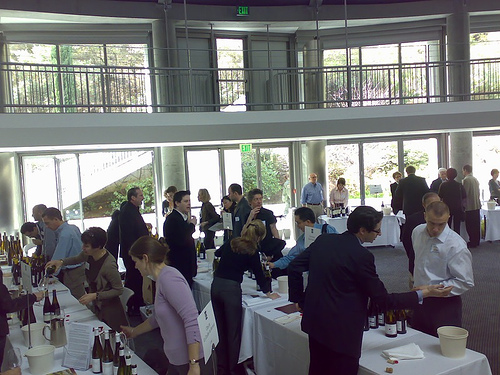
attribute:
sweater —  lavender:
[151, 261, 208, 365]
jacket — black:
[284, 225, 425, 372]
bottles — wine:
[367, 287, 412, 339]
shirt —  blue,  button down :
[302, 182, 324, 202]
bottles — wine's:
[385, 295, 438, 326]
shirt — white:
[404, 225, 475, 296]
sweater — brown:
[61, 244, 163, 322]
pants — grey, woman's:
[197, 277, 258, 373]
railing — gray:
[213, 70, 260, 110]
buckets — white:
[421, 306, 485, 373]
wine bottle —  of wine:
[380, 309, 397, 341]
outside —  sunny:
[38, 132, 405, 180]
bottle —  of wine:
[37, 290, 54, 345]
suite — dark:
[269, 188, 431, 365]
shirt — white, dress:
[409, 218, 476, 303]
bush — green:
[242, 152, 279, 194]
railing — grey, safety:
[0, 53, 499, 115]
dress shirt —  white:
[410, 226, 478, 309]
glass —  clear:
[116, 319, 129, 358]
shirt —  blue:
[298, 179, 323, 211]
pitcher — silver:
[9, 274, 104, 363]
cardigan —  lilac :
[151, 272, 203, 342]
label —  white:
[381, 321, 402, 336]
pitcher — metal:
[41, 314, 68, 349]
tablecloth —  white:
[247, 309, 309, 372]